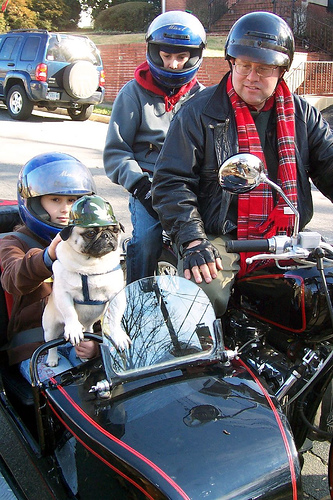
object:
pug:
[41, 195, 128, 366]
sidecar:
[1, 192, 301, 499]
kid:
[0, 149, 105, 347]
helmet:
[15, 149, 95, 245]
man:
[150, 13, 331, 321]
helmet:
[222, 11, 296, 71]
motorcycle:
[119, 219, 333, 479]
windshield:
[98, 275, 230, 383]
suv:
[0, 30, 108, 124]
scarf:
[222, 73, 297, 270]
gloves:
[182, 237, 223, 288]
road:
[0, 101, 333, 239]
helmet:
[63, 189, 118, 228]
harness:
[59, 259, 126, 307]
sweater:
[102, 62, 209, 190]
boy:
[102, 9, 213, 276]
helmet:
[143, 8, 207, 95]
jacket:
[150, 69, 331, 249]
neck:
[230, 86, 279, 122]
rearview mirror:
[217, 154, 266, 194]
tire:
[67, 60, 100, 101]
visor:
[28, 156, 99, 205]